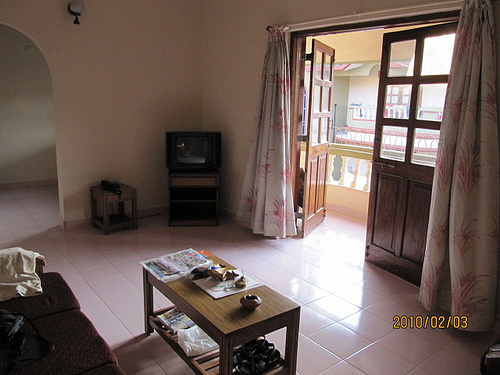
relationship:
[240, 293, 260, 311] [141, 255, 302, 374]
ashtray on table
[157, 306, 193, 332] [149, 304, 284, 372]
newpaper on shelf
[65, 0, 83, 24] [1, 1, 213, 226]
fixture on wall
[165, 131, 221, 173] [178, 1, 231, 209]
tv in corner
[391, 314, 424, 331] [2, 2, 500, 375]
year of picture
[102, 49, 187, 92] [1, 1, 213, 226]
part of wall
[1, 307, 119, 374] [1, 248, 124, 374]
section of sofa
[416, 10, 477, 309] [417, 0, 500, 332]
patch of curtains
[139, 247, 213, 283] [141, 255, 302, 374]
paper on table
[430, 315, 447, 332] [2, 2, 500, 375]
month of picture